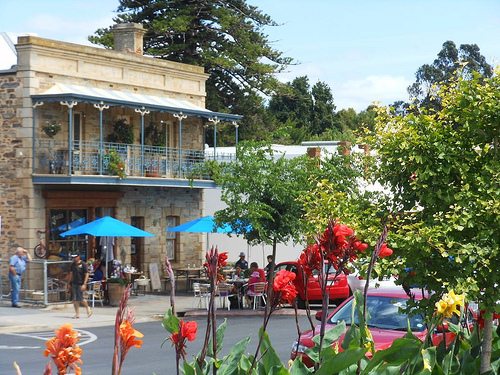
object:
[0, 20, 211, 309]
building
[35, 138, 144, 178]
railing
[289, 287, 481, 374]
car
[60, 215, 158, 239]
umbrella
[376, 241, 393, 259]
flowers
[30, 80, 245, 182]
building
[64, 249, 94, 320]
man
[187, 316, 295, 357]
road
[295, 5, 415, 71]
sky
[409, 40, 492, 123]
tree